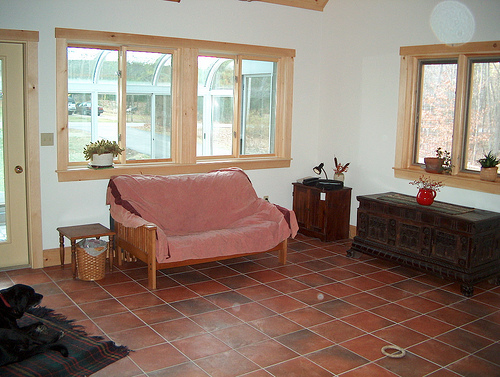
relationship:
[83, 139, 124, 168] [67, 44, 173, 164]
plant in window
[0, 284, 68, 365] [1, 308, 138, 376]
dog on blanket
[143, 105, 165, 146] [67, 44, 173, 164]
part of window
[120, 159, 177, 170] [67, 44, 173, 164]
edge of window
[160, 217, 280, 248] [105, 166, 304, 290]
edge of couch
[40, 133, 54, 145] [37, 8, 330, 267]
switch on wall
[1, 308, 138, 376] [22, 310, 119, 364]
blanket with stripes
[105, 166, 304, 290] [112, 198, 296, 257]
couch with arms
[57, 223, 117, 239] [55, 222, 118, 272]
top of table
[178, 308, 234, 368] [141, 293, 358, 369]
tiles of floor